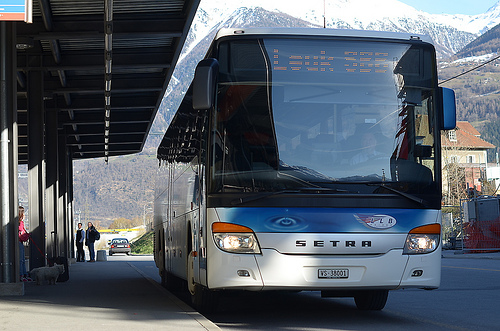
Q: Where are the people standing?
A: On the sidewalk.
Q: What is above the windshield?
A: The marquee display.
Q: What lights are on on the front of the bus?
A: The headlights.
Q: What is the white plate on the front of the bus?
A: The license plate.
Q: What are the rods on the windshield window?
A: Windshield wipers.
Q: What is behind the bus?
A: A car.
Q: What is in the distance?
A: Mountains.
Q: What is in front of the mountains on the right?
A: Houses.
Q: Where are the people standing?
A: Under the canopy of the station.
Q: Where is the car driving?
A: In the street.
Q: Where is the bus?
A: On the road.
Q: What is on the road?
A: A bus.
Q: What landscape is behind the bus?
A: Mountains.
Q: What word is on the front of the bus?
A: Setra.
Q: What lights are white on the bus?
A: Head lights.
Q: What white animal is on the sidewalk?
A: Dog.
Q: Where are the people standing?
A: On the sidewalk.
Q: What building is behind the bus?
A: House.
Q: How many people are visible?
A: Four.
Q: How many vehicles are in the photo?
A: Two.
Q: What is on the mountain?
A: Snow.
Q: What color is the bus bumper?
A: White.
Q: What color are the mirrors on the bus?
A: Blue.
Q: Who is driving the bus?
A: The man.